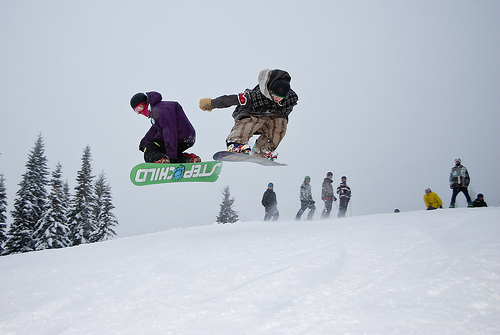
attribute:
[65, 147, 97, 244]
tree — tall, slender, evergreen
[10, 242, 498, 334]
snow — powdery, cold, melting, sprawling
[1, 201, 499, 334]
slopes — gentle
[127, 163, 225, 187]
snowboard — full sized, graphical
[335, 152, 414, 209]
ground — snowcovered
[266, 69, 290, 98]
hat — green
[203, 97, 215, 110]
gloves — tan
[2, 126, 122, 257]
trees — are conifer, are majestic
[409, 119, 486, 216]
man — limber, trained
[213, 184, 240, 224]
pine tree — snowy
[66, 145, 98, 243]
pine tree — snowy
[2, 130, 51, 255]
pine tree — snowy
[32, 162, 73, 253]
pine tree — snowy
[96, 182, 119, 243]
pine tree — snowy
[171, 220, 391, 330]
tracks — small, animal, numerous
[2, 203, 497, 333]
snow — cold, white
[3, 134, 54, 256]
tree — tall, conifer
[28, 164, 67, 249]
tree — conifer, tall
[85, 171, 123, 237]
tree — tall, conifer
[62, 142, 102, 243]
tree — conifer, tall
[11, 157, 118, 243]
snow — chunky, trail-beaten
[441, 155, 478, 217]
man — an adult, dramatic, white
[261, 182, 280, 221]
man — eager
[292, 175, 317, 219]
man — eager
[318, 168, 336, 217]
man — eager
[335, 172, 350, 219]
man — eager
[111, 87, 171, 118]
glasses — are uv-treated, are protective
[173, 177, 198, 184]
board edge — carved, smooth, oblique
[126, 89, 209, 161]
man — kneeling, snowboarding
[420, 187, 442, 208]
person — brave, distant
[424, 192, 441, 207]
coat — yellow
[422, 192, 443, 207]
snow jacket — warm, down-filled, struggling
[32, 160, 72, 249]
tree — beautiful, tall, slender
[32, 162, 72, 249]
snow — white, soft, frosted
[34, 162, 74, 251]
leaves — are beautiful, are green, are evergreen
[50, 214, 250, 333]
hill — snow-covered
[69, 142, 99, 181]
sky — misty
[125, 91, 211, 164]
snowboarder — squatting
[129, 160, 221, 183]
snowboard — green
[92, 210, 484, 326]
hill — steep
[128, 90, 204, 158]
snowboarder — young, fearless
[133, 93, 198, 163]
man — tense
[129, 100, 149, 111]
goggles — reflective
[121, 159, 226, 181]
snowboard — wooden, painted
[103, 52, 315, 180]
snowboarders — are male, are airbourne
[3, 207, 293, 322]
hill — snow-covered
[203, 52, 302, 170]
man — leaning, thrusting, ski-clad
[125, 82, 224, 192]
snowboarder — adolescent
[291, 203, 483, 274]
snow — cold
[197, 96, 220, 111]
hand — parrallel to the ground, outreached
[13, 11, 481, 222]
wind — frigid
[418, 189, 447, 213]
man — spirited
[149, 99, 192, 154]
jacket — purple